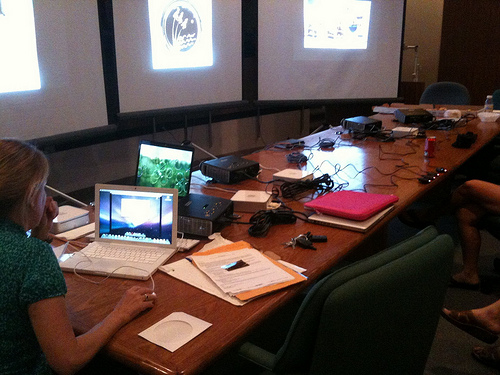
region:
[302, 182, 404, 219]
red laptop cover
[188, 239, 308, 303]
orange folder with white paper on top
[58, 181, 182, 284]
white open laptop with blue background on the screen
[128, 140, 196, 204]
black laptop with green screen background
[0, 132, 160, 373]
blonde woman wearing a green shirt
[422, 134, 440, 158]
red aluminum soda can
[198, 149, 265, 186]
black projector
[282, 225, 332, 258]
key chain with black vehicle fob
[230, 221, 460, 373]
empty green armchair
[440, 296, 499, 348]
foot wearing a brown leather sandal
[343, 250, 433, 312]
edge of a chair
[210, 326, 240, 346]
edge of a table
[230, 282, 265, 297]
edge of a file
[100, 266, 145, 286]
edge of a laptop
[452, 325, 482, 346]
sole of a sandal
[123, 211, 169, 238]
monitor of a screen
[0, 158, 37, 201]
hair of a lady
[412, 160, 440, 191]
part of some cables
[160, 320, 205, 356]
part of a paper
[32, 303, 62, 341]
part of a bicep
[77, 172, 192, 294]
the girl is using a laptop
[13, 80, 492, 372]
she is seated at a large conference table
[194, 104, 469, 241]
all types of gadgets are on the table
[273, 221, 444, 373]
this chair is green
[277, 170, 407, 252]
th book is red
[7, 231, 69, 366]
the girl is dressed in green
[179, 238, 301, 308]
the folder is orange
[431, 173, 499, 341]
another person is in the room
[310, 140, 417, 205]
wires are running everywhere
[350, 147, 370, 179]
the table is made of wood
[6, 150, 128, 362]
Person sitting at a table.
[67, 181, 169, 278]
The laptop is white.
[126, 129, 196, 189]
The laptop is black.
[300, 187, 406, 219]
The folder is red.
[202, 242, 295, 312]
Papers on top of an envelope.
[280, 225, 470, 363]
The chair is black.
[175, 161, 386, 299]
The table is wooden.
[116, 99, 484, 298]
The table is cluttered.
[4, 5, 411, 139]
Items being projected on screens.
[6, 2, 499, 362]
Picture was taken at a meeting.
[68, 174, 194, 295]
laptop is white and illuminated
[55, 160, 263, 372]
laptop is white and illuminated